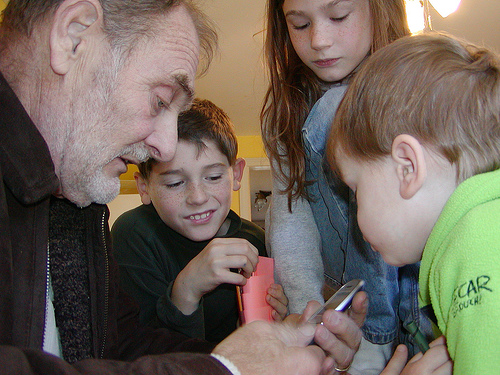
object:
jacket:
[264, 78, 424, 343]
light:
[405, 0, 478, 32]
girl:
[256, 0, 405, 375]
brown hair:
[258, 0, 407, 206]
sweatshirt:
[266, 105, 325, 319]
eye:
[206, 174, 222, 182]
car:
[25, 5, 216, 217]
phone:
[305, 278, 369, 326]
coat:
[3, 87, 229, 375]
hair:
[324, 34, 500, 181]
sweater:
[265, 86, 347, 311]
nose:
[185, 184, 211, 207]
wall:
[107, 0, 270, 225]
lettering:
[448, 272, 493, 317]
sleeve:
[431, 228, 499, 374]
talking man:
[3, 0, 497, 375]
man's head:
[0, 0, 199, 205]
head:
[1, 0, 216, 208]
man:
[3, 0, 369, 375]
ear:
[43, 0, 105, 76]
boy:
[108, 89, 267, 353]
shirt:
[43, 253, 72, 357]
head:
[325, 27, 499, 266]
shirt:
[415, 170, 497, 373]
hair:
[134, 87, 237, 180]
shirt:
[108, 201, 267, 367]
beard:
[53, 71, 148, 207]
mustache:
[123, 141, 150, 162]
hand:
[214, 317, 325, 373]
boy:
[323, 31, 497, 375]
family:
[0, 0, 498, 373]